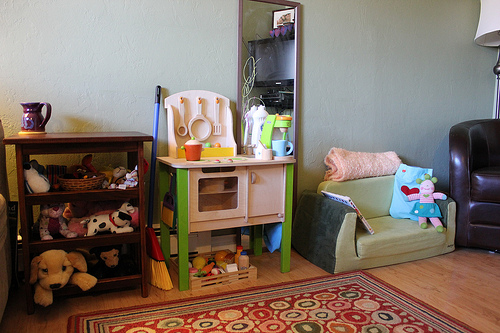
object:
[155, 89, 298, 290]
kitchen playset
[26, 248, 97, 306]
dog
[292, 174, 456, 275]
couch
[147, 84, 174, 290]
broom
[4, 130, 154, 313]
shelving unit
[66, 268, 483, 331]
rug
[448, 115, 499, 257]
couch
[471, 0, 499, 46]
lamp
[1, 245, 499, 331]
floor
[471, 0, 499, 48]
lamp shade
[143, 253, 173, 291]
thistles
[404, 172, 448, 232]
doll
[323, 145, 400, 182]
blanket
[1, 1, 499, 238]
wall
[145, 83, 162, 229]
handle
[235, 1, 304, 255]
mirror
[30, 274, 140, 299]
shelf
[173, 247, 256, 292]
crate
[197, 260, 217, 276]
play food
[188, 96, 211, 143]
cooking pan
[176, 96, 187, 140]
spoon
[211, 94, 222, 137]
spatula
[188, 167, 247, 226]
oven door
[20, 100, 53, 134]
cup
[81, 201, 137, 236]
stuffed animal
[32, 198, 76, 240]
stuffed animal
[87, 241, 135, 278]
stuffed animal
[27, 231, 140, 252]
shelf